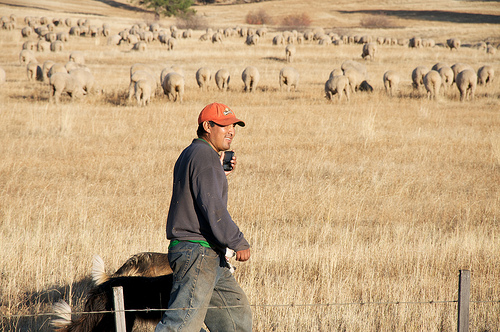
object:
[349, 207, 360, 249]
stalks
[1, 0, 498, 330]
field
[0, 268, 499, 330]
fence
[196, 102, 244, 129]
red cap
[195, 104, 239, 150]
man's head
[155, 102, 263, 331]
man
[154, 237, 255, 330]
jeans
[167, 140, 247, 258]
sweatshirt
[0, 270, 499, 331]
wooden fence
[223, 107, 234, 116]
symbol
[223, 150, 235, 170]
cellphone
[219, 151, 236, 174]
hand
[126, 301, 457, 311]
barbed wire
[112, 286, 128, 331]
fence posts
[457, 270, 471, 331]
fence posts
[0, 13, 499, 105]
herd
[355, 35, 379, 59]
sheep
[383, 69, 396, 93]
sheep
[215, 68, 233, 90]
sheep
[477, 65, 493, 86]
sheep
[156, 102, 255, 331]
farmer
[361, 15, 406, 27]
tree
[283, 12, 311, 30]
tree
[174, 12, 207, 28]
tree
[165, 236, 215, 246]
undershirt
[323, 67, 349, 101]
elephants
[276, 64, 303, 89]
elephants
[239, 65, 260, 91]
elephants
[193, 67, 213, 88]
elephants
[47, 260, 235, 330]
sheepdog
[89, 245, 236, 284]
sheepdog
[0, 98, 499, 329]
hay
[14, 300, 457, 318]
wire